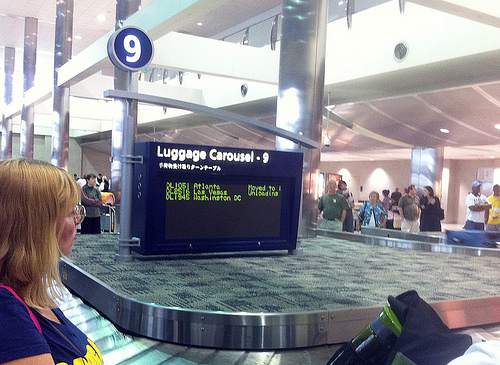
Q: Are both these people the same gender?
A: Yes, all the people are female.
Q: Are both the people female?
A: Yes, all the people are female.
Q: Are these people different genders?
A: No, all the people are female.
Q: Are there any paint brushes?
A: No, there are no paint brushes.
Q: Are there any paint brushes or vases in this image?
A: No, there are no paint brushes or vases.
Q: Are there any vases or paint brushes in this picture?
A: No, there are no paint brushes or vases.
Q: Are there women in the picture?
A: Yes, there is a woman.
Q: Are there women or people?
A: Yes, there is a woman.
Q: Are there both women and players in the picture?
A: No, there is a woman but no players.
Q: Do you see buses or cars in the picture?
A: No, there are no cars or buses.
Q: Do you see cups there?
A: Yes, there is a cup.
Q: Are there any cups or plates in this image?
A: Yes, there is a cup.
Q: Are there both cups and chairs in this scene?
A: No, there is a cup but no chairs.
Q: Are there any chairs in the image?
A: No, there are no chairs.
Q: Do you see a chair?
A: No, there are no chairs.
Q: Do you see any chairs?
A: No, there are no chairs.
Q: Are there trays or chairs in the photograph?
A: No, there are no chairs or trays.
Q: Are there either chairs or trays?
A: No, there are no chairs or trays.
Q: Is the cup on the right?
A: Yes, the cup is on the right of the image.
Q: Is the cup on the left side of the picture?
A: No, the cup is on the right of the image.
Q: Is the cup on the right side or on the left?
A: The cup is on the right of the image.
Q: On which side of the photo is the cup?
A: The cup is on the right of the image.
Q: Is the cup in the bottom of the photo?
A: Yes, the cup is in the bottom of the image.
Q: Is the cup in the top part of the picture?
A: No, the cup is in the bottom of the image.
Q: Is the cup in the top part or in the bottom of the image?
A: The cup is in the bottom of the image.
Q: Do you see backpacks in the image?
A: Yes, there is a backpack.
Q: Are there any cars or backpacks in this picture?
A: Yes, there is a backpack.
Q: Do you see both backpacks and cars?
A: No, there is a backpack but no cars.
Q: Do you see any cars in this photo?
A: No, there are no cars.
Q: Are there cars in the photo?
A: No, there are no cars.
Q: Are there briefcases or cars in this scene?
A: No, there are no cars or briefcases.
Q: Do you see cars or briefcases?
A: No, there are no cars or briefcases.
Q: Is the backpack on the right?
A: Yes, the backpack is on the right of the image.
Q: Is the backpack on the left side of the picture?
A: No, the backpack is on the right of the image.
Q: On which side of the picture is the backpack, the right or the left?
A: The backpack is on the right of the image.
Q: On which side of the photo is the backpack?
A: The backpack is on the right of the image.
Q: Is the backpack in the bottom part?
A: Yes, the backpack is in the bottom of the image.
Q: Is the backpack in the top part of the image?
A: No, the backpack is in the bottom of the image.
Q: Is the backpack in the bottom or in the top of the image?
A: The backpack is in the bottom of the image.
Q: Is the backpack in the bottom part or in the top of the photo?
A: The backpack is in the bottom of the image.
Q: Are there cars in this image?
A: No, there are no cars.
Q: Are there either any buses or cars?
A: No, there are no cars or buses.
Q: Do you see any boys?
A: No, there are no boys.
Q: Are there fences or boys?
A: No, there are no boys or fences.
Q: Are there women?
A: Yes, there is a woman.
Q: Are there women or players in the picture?
A: Yes, there is a woman.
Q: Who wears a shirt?
A: The woman wears a shirt.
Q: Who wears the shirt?
A: The woman wears a shirt.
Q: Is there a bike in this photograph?
A: No, there are no bikes.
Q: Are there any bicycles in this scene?
A: No, there are no bicycles.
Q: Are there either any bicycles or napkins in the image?
A: No, there are no bicycles or napkins.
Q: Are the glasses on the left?
A: Yes, the glasses are on the left of the image.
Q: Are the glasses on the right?
A: No, the glasses are on the left of the image.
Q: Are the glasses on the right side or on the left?
A: The glasses are on the left of the image.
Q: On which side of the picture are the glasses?
A: The glasses are on the left of the image.